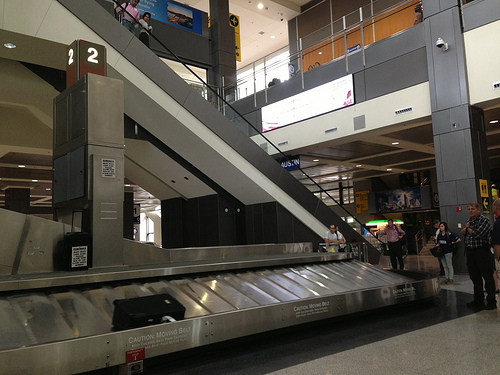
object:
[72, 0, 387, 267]
stair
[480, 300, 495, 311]
foot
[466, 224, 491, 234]
arm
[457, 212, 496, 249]
shirt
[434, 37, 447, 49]
camera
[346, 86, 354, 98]
leaves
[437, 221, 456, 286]
woman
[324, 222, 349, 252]
people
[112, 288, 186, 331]
luggage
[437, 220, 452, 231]
hair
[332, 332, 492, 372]
tile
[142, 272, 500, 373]
floor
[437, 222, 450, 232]
head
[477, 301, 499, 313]
shoes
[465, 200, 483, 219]
head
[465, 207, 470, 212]
eye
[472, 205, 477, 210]
eye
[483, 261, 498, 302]
legs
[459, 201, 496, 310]
man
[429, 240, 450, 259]
bag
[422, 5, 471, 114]
wall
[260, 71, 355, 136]
sign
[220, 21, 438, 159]
wall